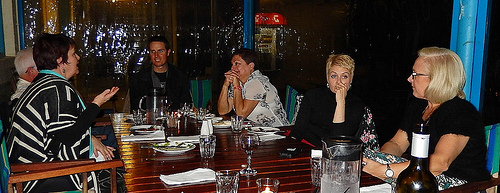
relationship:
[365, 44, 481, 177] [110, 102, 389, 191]
person sitting at table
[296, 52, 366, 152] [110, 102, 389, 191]
person sitting at table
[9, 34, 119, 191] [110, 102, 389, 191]
person sitting at table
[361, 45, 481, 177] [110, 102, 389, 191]
person sitting at table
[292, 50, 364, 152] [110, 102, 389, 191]
person sitting at table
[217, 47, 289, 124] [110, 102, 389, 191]
person sitting at table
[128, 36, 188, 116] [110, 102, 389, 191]
man sitting at table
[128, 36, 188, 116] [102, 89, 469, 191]
man sitting at table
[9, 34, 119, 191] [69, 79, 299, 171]
person sitting at table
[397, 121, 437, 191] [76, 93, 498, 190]
bottle on table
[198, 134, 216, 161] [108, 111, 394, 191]
glass on table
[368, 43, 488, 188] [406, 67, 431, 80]
woman has eye glasses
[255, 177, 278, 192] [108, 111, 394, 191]
cup on table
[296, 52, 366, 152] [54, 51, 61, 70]
person wearing earring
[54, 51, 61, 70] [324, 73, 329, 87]
earring in ear